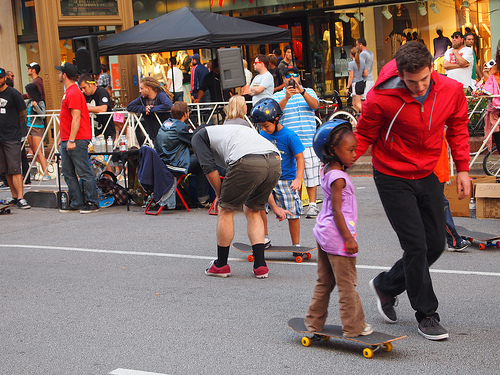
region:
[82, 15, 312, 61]
a black canopy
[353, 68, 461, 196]
a man wearing a red jacket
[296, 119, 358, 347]
a young girl riding a skateboard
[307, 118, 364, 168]
a young girl wearing a helmet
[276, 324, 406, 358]
a skateboard with yellow wheels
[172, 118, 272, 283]
a man bent over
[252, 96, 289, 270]
a young boy with one foot on a skateboard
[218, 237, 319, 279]
a skateboard with red wheels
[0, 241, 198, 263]
a white line painted on the pavement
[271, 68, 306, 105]
a man holding a cell phone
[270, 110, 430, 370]
little girl on skateboard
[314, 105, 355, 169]
little girl wearing helmet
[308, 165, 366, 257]
little girl wearing purple shirt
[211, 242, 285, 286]
man wearing red shoes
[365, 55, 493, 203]
man wearing a red sweater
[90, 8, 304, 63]
large black canvas canopy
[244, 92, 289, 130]
little boy wearing a helmet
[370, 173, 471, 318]
man wearing black sweats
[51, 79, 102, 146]
man wearing a red shirt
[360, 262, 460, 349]
man wearing black shoes